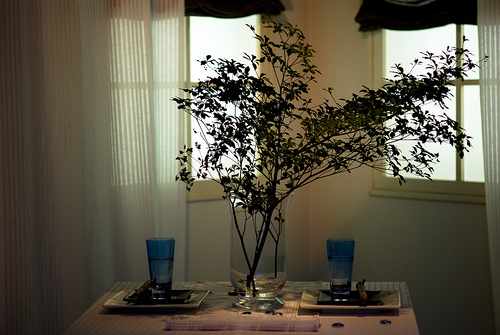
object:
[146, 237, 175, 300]
clear glass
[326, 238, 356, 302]
clear glass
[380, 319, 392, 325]
leaf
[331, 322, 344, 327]
leaf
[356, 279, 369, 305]
chop sticks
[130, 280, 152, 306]
chop sticks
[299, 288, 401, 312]
plate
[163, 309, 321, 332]
napkins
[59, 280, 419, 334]
table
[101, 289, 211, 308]
plate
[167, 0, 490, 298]
plant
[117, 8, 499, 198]
pizza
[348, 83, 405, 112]
leaves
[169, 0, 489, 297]
tree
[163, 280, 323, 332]
placemat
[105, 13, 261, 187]
window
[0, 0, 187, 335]
curtain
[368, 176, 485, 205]
window sill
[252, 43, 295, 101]
limbs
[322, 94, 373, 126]
leaves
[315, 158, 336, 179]
limb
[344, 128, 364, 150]
limb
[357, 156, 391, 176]
limb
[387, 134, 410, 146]
limb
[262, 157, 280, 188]
limb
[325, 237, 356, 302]
vase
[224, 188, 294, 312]
vase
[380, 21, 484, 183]
window